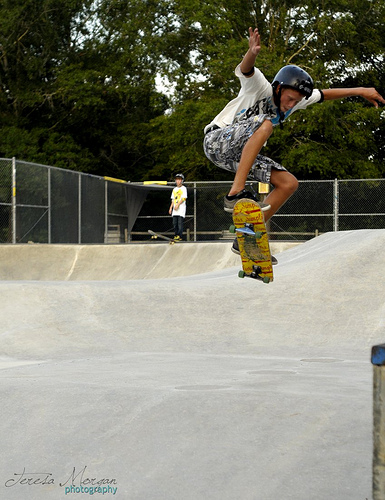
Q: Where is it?
A: This is at the skate park.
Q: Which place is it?
A: It is a skate park.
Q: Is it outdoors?
A: Yes, it is outdoors.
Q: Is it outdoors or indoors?
A: It is outdoors.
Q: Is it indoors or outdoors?
A: It is outdoors.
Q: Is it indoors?
A: No, it is outdoors.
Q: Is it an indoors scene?
A: No, it is outdoors.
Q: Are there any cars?
A: No, there are no cars.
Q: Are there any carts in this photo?
A: No, there are no carts.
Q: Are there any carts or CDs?
A: No, there are no carts or cds.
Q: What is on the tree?
A: The leaves are on the tree.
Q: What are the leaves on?
A: The leaves are on the tree.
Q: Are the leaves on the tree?
A: Yes, the leaves are on the tree.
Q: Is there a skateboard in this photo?
A: Yes, there is a skateboard.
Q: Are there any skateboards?
A: Yes, there is a skateboard.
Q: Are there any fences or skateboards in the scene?
A: Yes, there is a skateboard.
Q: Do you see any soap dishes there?
A: No, there are no soap dishes.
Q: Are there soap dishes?
A: No, there are no soap dishes.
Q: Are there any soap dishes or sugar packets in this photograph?
A: No, there are no soap dishes or sugar packets.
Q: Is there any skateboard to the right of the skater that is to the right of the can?
A: Yes, there is a skateboard to the right of the skater.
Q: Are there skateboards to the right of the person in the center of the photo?
A: Yes, there is a skateboard to the right of the skater.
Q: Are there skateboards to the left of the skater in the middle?
A: No, the skateboard is to the right of the skater.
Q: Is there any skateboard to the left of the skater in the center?
A: No, the skateboard is to the right of the skater.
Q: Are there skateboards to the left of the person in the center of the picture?
A: No, the skateboard is to the right of the skater.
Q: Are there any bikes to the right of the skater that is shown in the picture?
A: No, there is a skateboard to the right of the skater.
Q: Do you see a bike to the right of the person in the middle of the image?
A: No, there is a skateboard to the right of the skater.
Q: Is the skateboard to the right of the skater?
A: Yes, the skateboard is to the right of the skater.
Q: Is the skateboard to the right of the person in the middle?
A: Yes, the skateboard is to the right of the skater.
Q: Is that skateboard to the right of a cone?
A: No, the skateboard is to the right of the skater.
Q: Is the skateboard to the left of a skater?
A: No, the skateboard is to the right of a skater.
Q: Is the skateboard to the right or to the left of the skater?
A: The skateboard is to the right of the skater.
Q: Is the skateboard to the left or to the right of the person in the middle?
A: The skateboard is to the right of the skater.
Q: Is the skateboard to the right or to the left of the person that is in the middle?
A: The skateboard is to the right of the skater.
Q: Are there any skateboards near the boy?
A: Yes, there is a skateboard near the boy.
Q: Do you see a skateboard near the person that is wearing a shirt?
A: Yes, there is a skateboard near the boy.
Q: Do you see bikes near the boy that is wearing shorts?
A: No, there is a skateboard near the boy.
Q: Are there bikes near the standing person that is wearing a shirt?
A: No, there is a skateboard near the boy.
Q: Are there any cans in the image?
A: Yes, there is a can.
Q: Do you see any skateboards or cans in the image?
A: Yes, there is a can.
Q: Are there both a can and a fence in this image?
A: Yes, there are both a can and a fence.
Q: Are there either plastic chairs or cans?
A: Yes, there is a plastic can.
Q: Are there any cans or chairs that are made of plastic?
A: Yes, the can is made of plastic.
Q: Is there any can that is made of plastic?
A: Yes, there is a can that is made of plastic.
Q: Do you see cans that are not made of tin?
A: Yes, there is a can that is made of plastic.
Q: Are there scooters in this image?
A: No, there are no scooters.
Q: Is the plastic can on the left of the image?
A: Yes, the can is on the left of the image.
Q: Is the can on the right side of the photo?
A: No, the can is on the left of the image.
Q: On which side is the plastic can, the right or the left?
A: The can is on the left of the image.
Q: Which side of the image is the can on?
A: The can is on the left of the image.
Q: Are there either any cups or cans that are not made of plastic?
A: No, there is a can but it is made of plastic.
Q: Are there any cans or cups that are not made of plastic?
A: No, there is a can but it is made of plastic.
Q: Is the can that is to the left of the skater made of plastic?
A: Yes, the can is made of plastic.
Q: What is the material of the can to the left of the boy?
A: The can is made of plastic.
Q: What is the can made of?
A: The can is made of plastic.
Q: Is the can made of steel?
A: No, the can is made of plastic.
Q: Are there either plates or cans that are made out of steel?
A: No, there is a can but it is made of plastic.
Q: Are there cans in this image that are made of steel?
A: No, there is a can but it is made of plastic.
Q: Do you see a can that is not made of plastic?
A: No, there is a can but it is made of plastic.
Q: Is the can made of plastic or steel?
A: The can is made of plastic.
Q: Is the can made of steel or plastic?
A: The can is made of plastic.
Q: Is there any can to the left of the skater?
A: Yes, there is a can to the left of the skater.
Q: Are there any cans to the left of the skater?
A: Yes, there is a can to the left of the skater.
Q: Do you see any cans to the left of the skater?
A: Yes, there is a can to the left of the skater.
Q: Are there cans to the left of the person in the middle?
A: Yes, there is a can to the left of the skater.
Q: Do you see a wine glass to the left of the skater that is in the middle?
A: No, there is a can to the left of the skater.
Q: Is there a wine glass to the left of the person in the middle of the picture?
A: No, there is a can to the left of the skater.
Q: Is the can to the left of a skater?
A: Yes, the can is to the left of a skater.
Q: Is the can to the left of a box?
A: No, the can is to the left of a skater.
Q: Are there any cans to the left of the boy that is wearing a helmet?
A: Yes, there is a can to the left of the boy.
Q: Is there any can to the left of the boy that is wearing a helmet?
A: Yes, there is a can to the left of the boy.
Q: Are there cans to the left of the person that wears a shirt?
A: Yes, there is a can to the left of the boy.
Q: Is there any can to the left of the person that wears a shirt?
A: Yes, there is a can to the left of the boy.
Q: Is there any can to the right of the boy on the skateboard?
A: No, the can is to the left of the boy.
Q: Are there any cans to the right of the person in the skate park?
A: No, the can is to the left of the boy.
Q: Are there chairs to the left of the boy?
A: No, there is a can to the left of the boy.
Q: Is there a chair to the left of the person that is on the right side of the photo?
A: No, there is a can to the left of the boy.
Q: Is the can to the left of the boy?
A: Yes, the can is to the left of the boy.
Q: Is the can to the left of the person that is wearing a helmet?
A: Yes, the can is to the left of the boy.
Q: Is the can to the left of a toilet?
A: No, the can is to the left of the boy.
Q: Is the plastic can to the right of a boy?
A: No, the can is to the left of a boy.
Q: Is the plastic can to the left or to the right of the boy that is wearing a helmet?
A: The can is to the left of the boy.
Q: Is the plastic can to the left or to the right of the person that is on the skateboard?
A: The can is to the left of the boy.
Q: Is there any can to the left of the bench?
A: Yes, there is a can to the left of the bench.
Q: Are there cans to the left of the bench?
A: Yes, there is a can to the left of the bench.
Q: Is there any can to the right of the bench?
A: No, the can is to the left of the bench.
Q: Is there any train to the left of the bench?
A: No, there is a can to the left of the bench.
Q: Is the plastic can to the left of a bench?
A: Yes, the can is to the left of a bench.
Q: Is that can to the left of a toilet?
A: No, the can is to the left of a bench.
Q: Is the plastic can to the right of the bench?
A: No, the can is to the left of the bench.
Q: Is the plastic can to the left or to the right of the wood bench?
A: The can is to the left of the bench.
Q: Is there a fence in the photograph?
A: Yes, there is a fence.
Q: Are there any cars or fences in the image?
A: Yes, there is a fence.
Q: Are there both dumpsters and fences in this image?
A: No, there is a fence but no dumpsters.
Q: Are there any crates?
A: No, there are no crates.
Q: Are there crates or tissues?
A: No, there are no crates or tissues.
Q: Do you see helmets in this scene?
A: Yes, there is a helmet.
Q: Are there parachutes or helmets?
A: Yes, there is a helmet.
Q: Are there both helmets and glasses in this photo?
A: No, there is a helmet but no glasses.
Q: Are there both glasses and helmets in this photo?
A: No, there is a helmet but no glasses.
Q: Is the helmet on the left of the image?
A: No, the helmet is on the right of the image.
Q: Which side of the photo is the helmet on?
A: The helmet is on the right of the image.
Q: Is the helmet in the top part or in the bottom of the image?
A: The helmet is in the top of the image.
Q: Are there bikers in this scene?
A: No, there are no bikers.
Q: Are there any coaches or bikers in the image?
A: No, there are no bikers or coaches.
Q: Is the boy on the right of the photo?
A: Yes, the boy is on the right of the image.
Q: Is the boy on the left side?
A: No, the boy is on the right of the image.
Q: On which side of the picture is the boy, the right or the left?
A: The boy is on the right of the image.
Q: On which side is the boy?
A: The boy is on the right of the image.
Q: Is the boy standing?
A: Yes, the boy is standing.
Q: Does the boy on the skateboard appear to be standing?
A: Yes, the boy is standing.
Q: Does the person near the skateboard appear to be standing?
A: Yes, the boy is standing.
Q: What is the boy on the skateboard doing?
A: The boy is standing.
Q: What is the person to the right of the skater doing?
A: The boy is standing.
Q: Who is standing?
A: The boy is standing.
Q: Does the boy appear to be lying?
A: No, the boy is standing.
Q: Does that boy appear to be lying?
A: No, the boy is standing.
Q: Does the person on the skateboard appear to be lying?
A: No, the boy is standing.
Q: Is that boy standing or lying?
A: The boy is standing.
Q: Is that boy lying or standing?
A: The boy is standing.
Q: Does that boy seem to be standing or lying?
A: The boy is standing.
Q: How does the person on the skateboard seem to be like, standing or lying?
A: The boy is standing.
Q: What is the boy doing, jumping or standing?
A: The boy is standing.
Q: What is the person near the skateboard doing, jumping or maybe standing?
A: The boy is standing.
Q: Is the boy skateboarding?
A: Yes, the boy is skateboarding.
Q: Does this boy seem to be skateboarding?
A: Yes, the boy is skateboarding.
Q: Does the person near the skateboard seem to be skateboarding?
A: Yes, the boy is skateboarding.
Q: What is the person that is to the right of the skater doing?
A: The boy is skateboarding.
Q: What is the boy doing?
A: The boy is skateboarding.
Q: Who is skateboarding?
A: The boy is skateboarding.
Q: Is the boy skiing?
A: No, the boy is skateboarding.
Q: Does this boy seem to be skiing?
A: No, the boy is skateboarding.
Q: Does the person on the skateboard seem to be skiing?
A: No, the boy is skateboarding.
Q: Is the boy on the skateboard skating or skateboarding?
A: The boy is skateboarding.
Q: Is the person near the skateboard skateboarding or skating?
A: The boy is skateboarding.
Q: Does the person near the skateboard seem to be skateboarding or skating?
A: The boy is skateboarding.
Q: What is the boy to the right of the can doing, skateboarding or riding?
A: The boy is skateboarding.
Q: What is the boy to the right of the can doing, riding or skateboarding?
A: The boy is skateboarding.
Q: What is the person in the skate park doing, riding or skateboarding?
A: The boy is skateboarding.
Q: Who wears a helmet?
A: The boy wears a helmet.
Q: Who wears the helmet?
A: The boy wears a helmet.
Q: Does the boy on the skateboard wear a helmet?
A: Yes, the boy wears a helmet.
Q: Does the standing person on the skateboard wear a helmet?
A: Yes, the boy wears a helmet.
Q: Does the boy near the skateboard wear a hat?
A: No, the boy wears a helmet.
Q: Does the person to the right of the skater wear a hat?
A: No, the boy wears a helmet.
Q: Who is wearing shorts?
A: The boy is wearing shorts.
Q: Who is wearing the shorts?
A: The boy is wearing shorts.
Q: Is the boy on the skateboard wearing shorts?
A: Yes, the boy is wearing shorts.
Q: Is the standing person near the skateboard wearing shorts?
A: Yes, the boy is wearing shorts.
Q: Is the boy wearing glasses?
A: No, the boy is wearing shorts.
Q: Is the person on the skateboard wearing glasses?
A: No, the boy is wearing shorts.